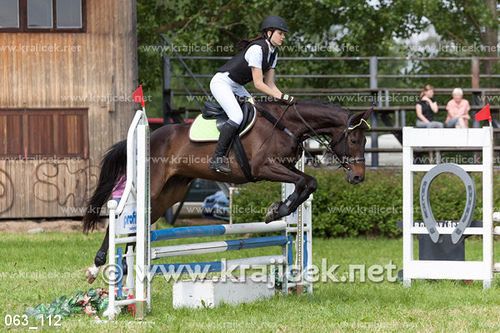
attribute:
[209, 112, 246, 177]
boot — black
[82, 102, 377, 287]
horse — jumping, brown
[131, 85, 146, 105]
flag — red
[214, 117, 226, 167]
boot — riding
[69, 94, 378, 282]
horse — brown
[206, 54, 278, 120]
pants — white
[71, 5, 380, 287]
horse — dark, brown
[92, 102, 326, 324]
hurdle — white, blue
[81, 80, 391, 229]
horse — jumping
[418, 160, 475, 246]
horseshoe sign — silver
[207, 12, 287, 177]
woman — riding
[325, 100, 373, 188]
head — brown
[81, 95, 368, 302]
horse — brown